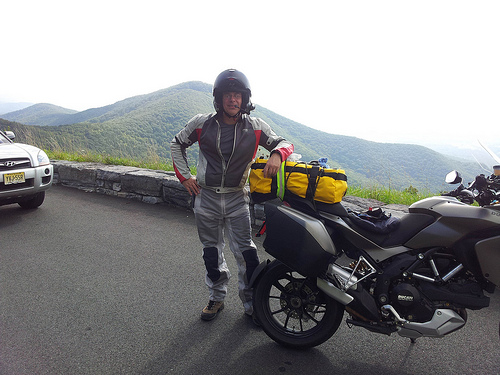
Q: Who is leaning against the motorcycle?
A: Man wearing gray jacket.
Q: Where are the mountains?
A: They are in the background.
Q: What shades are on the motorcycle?
A: Silver, gray and black.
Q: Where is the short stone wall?
A: Along the side of the road.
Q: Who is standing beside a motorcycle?
A: A man.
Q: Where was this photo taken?
A: On a road.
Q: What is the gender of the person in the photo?
A: Male.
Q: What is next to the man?
A: A motorcycle.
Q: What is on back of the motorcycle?
A: A bag.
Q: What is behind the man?
A: A wall.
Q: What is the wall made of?
A: Stone.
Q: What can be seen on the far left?
A: A car.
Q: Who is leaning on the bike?
A: Man.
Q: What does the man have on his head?
A: Helmet.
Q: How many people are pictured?
A: 1.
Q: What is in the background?
A: Mountain.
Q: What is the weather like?
A: Sunny.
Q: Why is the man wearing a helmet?
A: Safety.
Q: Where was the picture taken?
A: Road.